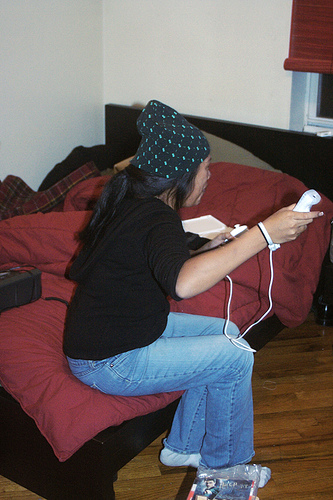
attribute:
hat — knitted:
[134, 94, 214, 176]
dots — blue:
[156, 127, 167, 144]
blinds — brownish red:
[287, 3, 331, 74]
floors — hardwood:
[12, 327, 332, 500]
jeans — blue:
[67, 316, 257, 461]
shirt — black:
[68, 190, 183, 361]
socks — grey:
[152, 445, 273, 487]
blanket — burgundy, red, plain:
[2, 161, 332, 456]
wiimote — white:
[224, 181, 324, 262]